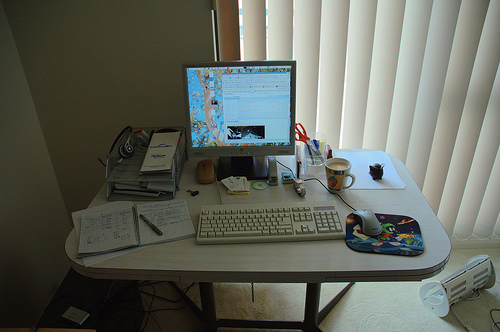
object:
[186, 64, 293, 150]
screen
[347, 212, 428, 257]
pad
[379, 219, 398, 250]
character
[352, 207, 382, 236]
mouse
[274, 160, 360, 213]
wire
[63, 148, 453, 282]
table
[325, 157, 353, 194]
cup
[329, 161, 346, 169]
coffee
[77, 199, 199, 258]
notebook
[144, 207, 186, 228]
writing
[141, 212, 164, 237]
pen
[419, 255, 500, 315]
heater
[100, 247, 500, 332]
floor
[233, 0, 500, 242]
blinds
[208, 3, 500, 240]
window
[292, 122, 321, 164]
scissors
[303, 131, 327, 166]
cup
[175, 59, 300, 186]
computer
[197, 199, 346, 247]
keyboard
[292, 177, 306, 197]
watch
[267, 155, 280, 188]
stapler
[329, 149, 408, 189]
paper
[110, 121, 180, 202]
tray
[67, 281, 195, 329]
cords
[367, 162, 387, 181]
figurine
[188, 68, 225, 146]
tree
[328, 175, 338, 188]
strawberry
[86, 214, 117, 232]
notes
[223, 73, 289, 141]
window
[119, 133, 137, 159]
headphones